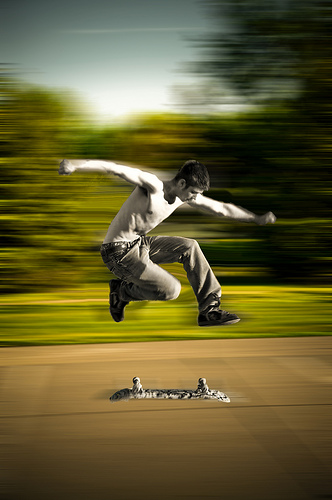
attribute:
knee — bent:
[156, 277, 181, 300]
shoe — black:
[107, 278, 129, 321]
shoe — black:
[198, 308, 239, 326]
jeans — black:
[100, 233, 222, 311]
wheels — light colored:
[131, 373, 143, 386]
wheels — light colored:
[197, 373, 207, 386]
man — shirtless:
[56, 156, 277, 332]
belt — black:
[86, 244, 139, 255]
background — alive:
[4, 43, 331, 365]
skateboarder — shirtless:
[59, 153, 275, 327]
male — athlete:
[59, 146, 279, 335]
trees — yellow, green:
[4, 141, 331, 281]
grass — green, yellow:
[0, 281, 330, 341]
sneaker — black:
[196, 309, 240, 326]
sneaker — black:
[106, 277, 132, 322]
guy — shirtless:
[58, 158, 275, 326]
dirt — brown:
[34, 419, 274, 491]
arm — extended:
[182, 191, 284, 230]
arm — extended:
[54, 154, 157, 193]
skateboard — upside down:
[106, 371, 242, 407]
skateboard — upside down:
[108, 373, 232, 408]